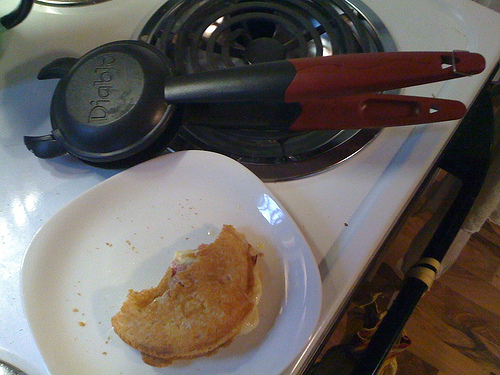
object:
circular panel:
[23, 39, 167, 168]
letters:
[81, 46, 128, 128]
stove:
[3, 0, 498, 373]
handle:
[174, 49, 487, 131]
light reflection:
[1, 171, 41, 282]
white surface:
[0, 4, 497, 374]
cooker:
[23, 0, 485, 183]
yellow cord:
[405, 254, 443, 294]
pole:
[330, 84, 499, 373]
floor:
[307, 166, 496, 373]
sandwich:
[109, 223, 265, 369]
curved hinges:
[24, 57, 72, 158]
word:
[82, 50, 126, 126]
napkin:
[401, 167, 497, 286]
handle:
[357, 146, 486, 374]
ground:
[218, 54, 260, 94]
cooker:
[20, 35, 489, 168]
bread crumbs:
[100, 237, 145, 261]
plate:
[21, 148, 326, 373]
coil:
[139, 0, 386, 167]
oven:
[266, 88, 490, 373]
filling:
[233, 255, 272, 359]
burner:
[128, 0, 400, 183]